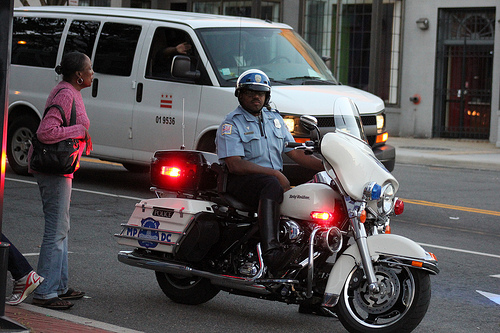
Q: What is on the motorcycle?
A: A policeman.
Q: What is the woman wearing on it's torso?
A: A pink sweater.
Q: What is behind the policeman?
A: A van.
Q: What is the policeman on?
A: A motorcycle.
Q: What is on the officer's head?
A: A helmet.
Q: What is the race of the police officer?
A: He's black.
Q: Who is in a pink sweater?
A: An elderly woman.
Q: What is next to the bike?
A: White cargo van.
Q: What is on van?
A: Row of windows.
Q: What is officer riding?
A: A bike.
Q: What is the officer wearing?
A: A uniform.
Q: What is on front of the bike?
A: Lights.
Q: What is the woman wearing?
A: A pink shirt.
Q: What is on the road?
A: A yellow line.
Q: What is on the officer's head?
A: A helmet.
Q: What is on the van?
A: Windows.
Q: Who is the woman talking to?
A: The police officer.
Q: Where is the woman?
A: Side of road.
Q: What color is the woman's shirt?
A: Pink.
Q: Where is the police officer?
A: On his bike.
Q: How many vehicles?
A: Two.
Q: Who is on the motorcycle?
A: Police officer.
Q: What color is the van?
A: White.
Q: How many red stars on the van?
A: Three.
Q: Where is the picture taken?
A: Street.